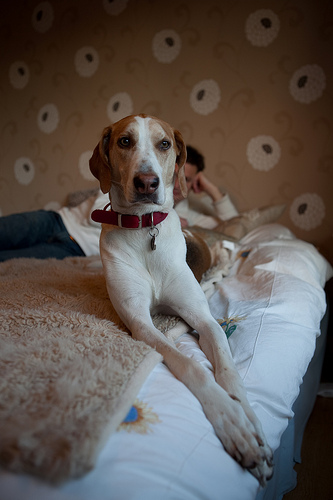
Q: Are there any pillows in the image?
A: Yes, there is a pillow.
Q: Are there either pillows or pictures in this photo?
A: Yes, there is a pillow.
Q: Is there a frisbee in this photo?
A: No, there are no frisbees.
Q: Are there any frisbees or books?
A: No, there are no frisbees or books.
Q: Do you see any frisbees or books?
A: No, there are no frisbees or books.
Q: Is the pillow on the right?
A: Yes, the pillow is on the right of the image.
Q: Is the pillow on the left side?
A: No, the pillow is on the right of the image.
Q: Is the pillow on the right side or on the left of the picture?
A: The pillow is on the right of the image.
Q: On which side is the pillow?
A: The pillow is on the right of the image.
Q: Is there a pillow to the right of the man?
A: Yes, there is a pillow to the right of the man.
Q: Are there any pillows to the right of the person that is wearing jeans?
A: Yes, there is a pillow to the right of the man.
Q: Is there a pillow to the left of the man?
A: No, the pillow is to the right of the man.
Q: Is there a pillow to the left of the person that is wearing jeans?
A: No, the pillow is to the right of the man.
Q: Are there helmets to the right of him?
A: No, there is a pillow to the right of the man.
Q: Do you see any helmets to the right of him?
A: No, there is a pillow to the right of the man.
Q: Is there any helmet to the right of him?
A: No, there is a pillow to the right of the man.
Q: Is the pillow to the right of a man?
A: Yes, the pillow is to the right of a man.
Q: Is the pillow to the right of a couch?
A: No, the pillow is to the right of a man.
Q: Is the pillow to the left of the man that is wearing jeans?
A: No, the pillow is to the right of the man.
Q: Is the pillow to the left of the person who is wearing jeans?
A: No, the pillow is to the right of the man.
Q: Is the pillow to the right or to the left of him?
A: The pillow is to the right of the man.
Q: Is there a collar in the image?
A: Yes, there is a collar.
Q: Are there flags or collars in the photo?
A: Yes, there is a collar.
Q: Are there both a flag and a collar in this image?
A: No, there is a collar but no flags.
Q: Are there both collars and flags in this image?
A: No, there is a collar but no flags.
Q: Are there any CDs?
A: No, there are no cds.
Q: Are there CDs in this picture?
A: No, there are no cds.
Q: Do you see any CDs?
A: No, there are no cds.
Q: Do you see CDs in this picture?
A: No, there are no cds.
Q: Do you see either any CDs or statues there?
A: No, there are no CDs or statues.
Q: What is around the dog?
A: The collar is around the dog.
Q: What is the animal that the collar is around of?
A: The animal is a dog.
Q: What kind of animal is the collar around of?
A: The collar is around the dog.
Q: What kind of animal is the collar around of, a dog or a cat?
A: The collar is around a dog.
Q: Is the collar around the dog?
A: Yes, the collar is around the dog.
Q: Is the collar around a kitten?
A: No, the collar is around the dog.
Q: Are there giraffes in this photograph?
A: No, there are no giraffes.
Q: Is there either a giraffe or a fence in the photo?
A: No, there are no giraffes or fences.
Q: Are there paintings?
A: No, there are no paintings.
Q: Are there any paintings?
A: No, there are no paintings.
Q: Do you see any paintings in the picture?
A: No, there are no paintings.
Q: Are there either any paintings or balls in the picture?
A: No, there are no paintings or balls.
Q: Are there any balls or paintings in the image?
A: No, there are no paintings or balls.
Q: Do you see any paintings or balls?
A: No, there are no paintings or balls.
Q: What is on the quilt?
A: The flower is on the quilt.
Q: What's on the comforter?
A: The flower is on the quilt.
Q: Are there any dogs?
A: Yes, there is a dog.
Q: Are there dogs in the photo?
A: Yes, there is a dog.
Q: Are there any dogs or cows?
A: Yes, there is a dog.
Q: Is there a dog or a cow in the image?
A: Yes, there is a dog.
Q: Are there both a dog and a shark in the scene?
A: No, there is a dog but no sharks.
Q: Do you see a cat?
A: No, there are no cats.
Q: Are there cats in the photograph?
A: No, there are no cats.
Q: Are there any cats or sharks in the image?
A: No, there are no cats or sharks.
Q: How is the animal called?
A: The animal is a dog.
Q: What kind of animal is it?
A: The animal is a dog.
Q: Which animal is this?
A: This is a dog.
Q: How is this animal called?
A: This is a dog.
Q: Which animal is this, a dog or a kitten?
A: This is a dog.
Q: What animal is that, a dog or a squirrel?
A: That is a dog.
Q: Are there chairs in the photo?
A: No, there are no chairs.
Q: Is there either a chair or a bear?
A: No, there are no chairs or bears.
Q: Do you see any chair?
A: No, there are no chairs.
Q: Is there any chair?
A: No, there are no chairs.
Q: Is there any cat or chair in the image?
A: No, there are no chairs or cats.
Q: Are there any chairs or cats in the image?
A: No, there are no chairs or cats.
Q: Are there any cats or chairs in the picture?
A: No, there are no chairs or cats.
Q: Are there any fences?
A: No, there are no fences.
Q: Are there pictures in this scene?
A: No, there are no pictures.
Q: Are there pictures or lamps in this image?
A: No, there are no pictures or lamps.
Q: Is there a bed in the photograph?
A: Yes, there is a bed.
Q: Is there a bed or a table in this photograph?
A: Yes, there is a bed.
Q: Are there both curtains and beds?
A: No, there is a bed but no curtains.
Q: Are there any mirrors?
A: No, there are no mirrors.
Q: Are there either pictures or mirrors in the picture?
A: No, there are no mirrors or pictures.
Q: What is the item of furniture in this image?
A: The piece of furniture is a bed.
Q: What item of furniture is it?
A: The piece of furniture is a bed.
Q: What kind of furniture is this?
A: That is a bed.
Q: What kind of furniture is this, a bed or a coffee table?
A: That is a bed.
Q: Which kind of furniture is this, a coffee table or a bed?
A: That is a bed.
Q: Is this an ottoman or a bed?
A: This is a bed.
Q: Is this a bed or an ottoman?
A: This is a bed.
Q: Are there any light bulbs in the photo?
A: No, there are no light bulbs.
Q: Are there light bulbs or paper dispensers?
A: No, there are no light bulbs or paper dispensers.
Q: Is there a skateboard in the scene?
A: No, there are no skateboards.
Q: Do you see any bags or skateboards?
A: No, there are no skateboards or bags.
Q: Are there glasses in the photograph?
A: No, there are no glasses.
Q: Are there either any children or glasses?
A: No, there are no glasses or children.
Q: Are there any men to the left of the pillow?
A: Yes, there is a man to the left of the pillow.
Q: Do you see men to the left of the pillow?
A: Yes, there is a man to the left of the pillow.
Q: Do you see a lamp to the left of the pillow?
A: No, there is a man to the left of the pillow.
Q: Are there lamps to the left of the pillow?
A: No, there is a man to the left of the pillow.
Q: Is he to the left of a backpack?
A: No, the man is to the left of the pillow.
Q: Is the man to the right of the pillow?
A: No, the man is to the left of the pillow.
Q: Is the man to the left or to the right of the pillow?
A: The man is to the left of the pillow.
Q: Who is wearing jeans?
A: The man is wearing jeans.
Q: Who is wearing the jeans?
A: The man is wearing jeans.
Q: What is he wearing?
A: The man is wearing jeans.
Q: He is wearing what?
A: The man is wearing jeans.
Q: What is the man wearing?
A: The man is wearing jeans.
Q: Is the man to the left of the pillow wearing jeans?
A: Yes, the man is wearing jeans.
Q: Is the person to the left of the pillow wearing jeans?
A: Yes, the man is wearing jeans.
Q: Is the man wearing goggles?
A: No, the man is wearing jeans.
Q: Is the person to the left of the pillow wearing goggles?
A: No, the man is wearing jeans.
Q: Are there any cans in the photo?
A: No, there are no cans.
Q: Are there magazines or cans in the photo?
A: No, there are no cans or magazines.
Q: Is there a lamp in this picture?
A: No, there are no lamps.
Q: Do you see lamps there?
A: No, there are no lamps.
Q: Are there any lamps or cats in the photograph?
A: No, there are no lamps or cats.